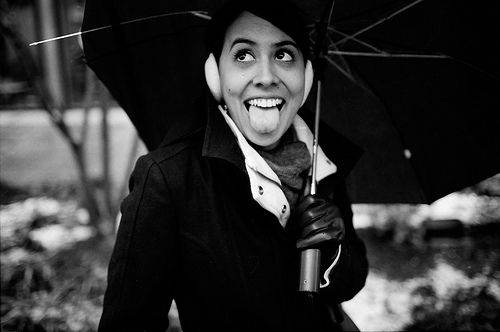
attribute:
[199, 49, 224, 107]
muff — white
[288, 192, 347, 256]
glove — black, dark colored, leather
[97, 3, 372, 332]
woman — smiling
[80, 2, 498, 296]
umbrella — dark, black, fabric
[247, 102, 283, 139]
tongue — sticking out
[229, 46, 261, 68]
eye — rolled up, looking up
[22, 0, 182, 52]
wire — metal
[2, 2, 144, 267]
tree — covered, small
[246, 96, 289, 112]
teeth — white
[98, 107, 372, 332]
jacket — black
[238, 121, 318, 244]
scarf — wrapped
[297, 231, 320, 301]
base — round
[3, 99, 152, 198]
wall — concrete